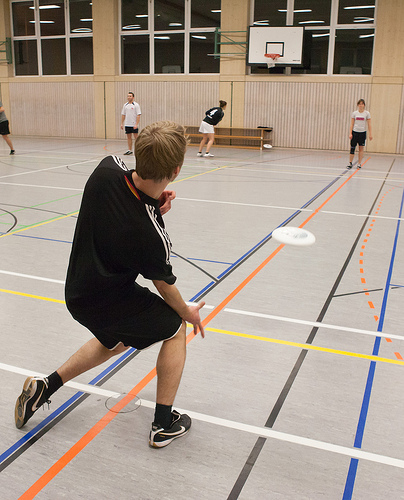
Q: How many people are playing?
A: Five.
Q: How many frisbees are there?
A: Two.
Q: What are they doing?
A: Playing frisbee.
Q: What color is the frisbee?
A: White.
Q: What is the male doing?
A: Throwing the frisbee.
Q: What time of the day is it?
A: Night.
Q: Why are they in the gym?
A: Playing.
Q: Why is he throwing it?
A: Part of the game.